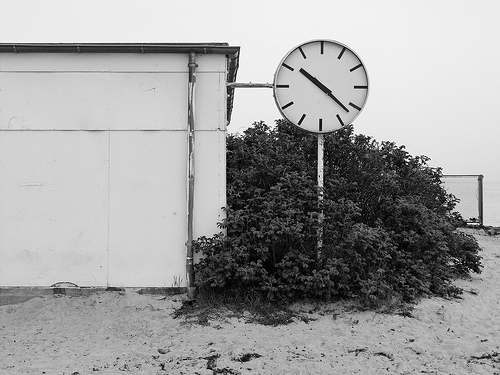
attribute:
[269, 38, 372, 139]
clock — standing, attached, white, large, thin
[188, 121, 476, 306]
bush — green, large, overgrown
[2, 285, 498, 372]
ground — white, sandy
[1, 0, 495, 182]
sky — clear, cloudy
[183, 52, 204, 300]
pipe — protruding, gray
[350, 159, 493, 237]
fence — gray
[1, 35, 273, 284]
building — white, painted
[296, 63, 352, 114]
hands — long, black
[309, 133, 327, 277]
pole — rusty, peeling